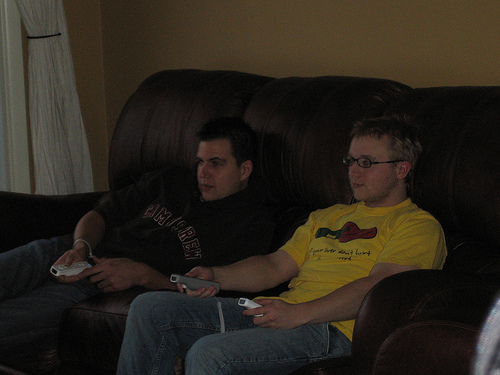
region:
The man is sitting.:
[101, 105, 458, 374]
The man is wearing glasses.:
[266, 112, 453, 374]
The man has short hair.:
[278, 99, 456, 374]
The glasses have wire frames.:
[268, 101, 454, 368]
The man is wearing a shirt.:
[243, 110, 450, 359]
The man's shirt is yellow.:
[238, 100, 458, 350]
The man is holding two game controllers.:
[154, 103, 455, 341]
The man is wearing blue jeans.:
[106, 110, 458, 374]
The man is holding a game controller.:
[0, 101, 272, 342]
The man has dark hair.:
[119, 84, 286, 235]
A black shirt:
[125, 201, 235, 268]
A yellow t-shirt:
[299, 202, 426, 335]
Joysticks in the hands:
[171, 262, 284, 332]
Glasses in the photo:
[330, 152, 412, 172]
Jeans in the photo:
[125, 286, 287, 361]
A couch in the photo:
[226, 73, 433, 135]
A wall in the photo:
[256, 2, 381, 69]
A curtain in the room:
[21, 52, 94, 179]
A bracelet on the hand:
[67, 226, 98, 261]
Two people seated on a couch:
[1, 109, 419, 373]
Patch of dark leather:
[148, 56, 201, 98]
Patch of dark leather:
[215, 64, 275, 104]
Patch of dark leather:
[293, 64, 344, 98]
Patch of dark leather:
[335, 69, 464, 119]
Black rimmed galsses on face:
[336, 152, 420, 169]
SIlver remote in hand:
[167, 268, 228, 306]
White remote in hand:
[233, 293, 280, 321]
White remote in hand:
[43, 241, 93, 289]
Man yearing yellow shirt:
[290, 156, 495, 365]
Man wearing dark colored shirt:
[75, 98, 246, 288]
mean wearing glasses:
[114, 113, 453, 373]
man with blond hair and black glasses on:
[120, 115, 447, 374]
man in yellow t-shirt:
[120, 115, 447, 374]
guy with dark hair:
[1, 119, 278, 334]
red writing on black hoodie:
[140, 202, 202, 262]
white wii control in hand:
[51, 257, 91, 277]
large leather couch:
[2, 69, 497, 367]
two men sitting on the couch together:
[0, 116, 448, 371]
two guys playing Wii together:
[0, 115, 447, 374]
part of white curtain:
[13, 3, 98, 195]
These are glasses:
[318, 145, 391, 177]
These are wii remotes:
[160, 240, 276, 320]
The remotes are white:
[162, 252, 261, 337]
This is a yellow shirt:
[243, 193, 417, 274]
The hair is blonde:
[315, 132, 475, 212]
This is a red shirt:
[146, 196, 186, 283]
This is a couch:
[108, 119, 191, 156]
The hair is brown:
[208, 129, 242, 152]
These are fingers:
[250, 285, 267, 320]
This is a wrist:
[289, 304, 301, 331]